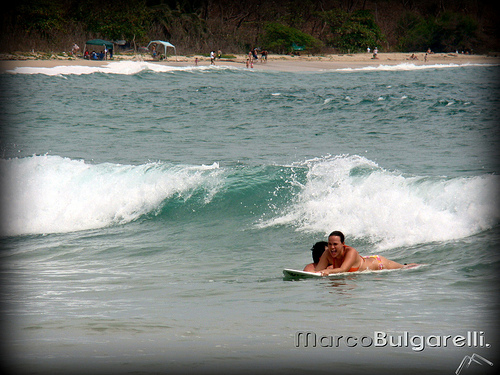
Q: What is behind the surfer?
A: A wave.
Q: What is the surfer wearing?
A: A bathing suit.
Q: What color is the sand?
A: Tan.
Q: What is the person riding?
A: A surfboard.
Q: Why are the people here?
A: For water sports.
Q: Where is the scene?
A: At the beach.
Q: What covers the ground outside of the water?
A: Sand.